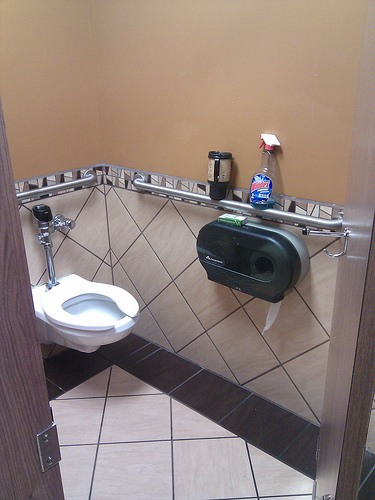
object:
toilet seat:
[43, 281, 139, 334]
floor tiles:
[42, 332, 374, 499]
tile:
[294, 238, 339, 340]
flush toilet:
[29, 203, 139, 353]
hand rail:
[133, 173, 343, 231]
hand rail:
[17, 169, 96, 203]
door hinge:
[35, 422, 62, 471]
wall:
[0, 0, 111, 402]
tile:
[168, 367, 246, 422]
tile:
[220, 394, 310, 459]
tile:
[279, 422, 375, 498]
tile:
[56, 365, 110, 399]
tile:
[90, 438, 174, 498]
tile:
[43, 349, 113, 393]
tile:
[245, 439, 314, 496]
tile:
[128, 347, 204, 394]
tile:
[229, 219, 338, 306]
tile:
[241, 365, 321, 441]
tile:
[281, 338, 330, 423]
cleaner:
[249, 133, 281, 209]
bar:
[133, 178, 342, 231]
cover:
[196, 219, 310, 302]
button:
[32, 203, 52, 221]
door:
[0, 106, 66, 500]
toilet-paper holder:
[195, 219, 310, 304]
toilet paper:
[261, 300, 283, 336]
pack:
[218, 213, 247, 227]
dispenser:
[195, 218, 309, 303]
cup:
[207, 151, 235, 200]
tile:
[48, 396, 105, 445]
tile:
[117, 344, 159, 370]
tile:
[99, 334, 149, 365]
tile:
[46, 376, 66, 401]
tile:
[107, 365, 173, 397]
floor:
[39, 331, 375, 500]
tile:
[174, 256, 242, 330]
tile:
[173, 329, 239, 387]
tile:
[241, 288, 329, 365]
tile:
[142, 198, 198, 281]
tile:
[146, 279, 206, 355]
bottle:
[248, 133, 280, 210]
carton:
[218, 213, 248, 227]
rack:
[302, 228, 352, 258]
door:
[316, 0, 375, 500]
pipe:
[31, 214, 75, 284]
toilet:
[0, 0, 371, 500]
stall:
[4, 6, 348, 500]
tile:
[205, 306, 281, 386]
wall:
[86, 3, 345, 429]